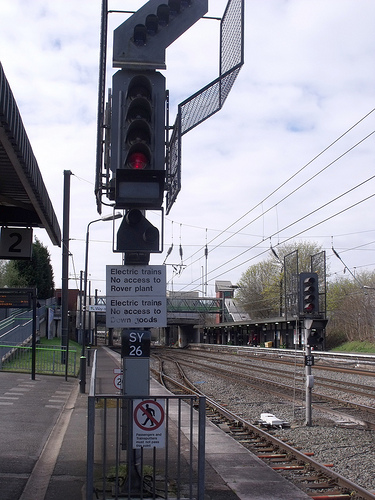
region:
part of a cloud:
[255, 73, 278, 116]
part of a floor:
[201, 435, 220, 456]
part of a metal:
[186, 450, 203, 490]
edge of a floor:
[230, 438, 250, 455]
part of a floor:
[231, 436, 262, 454]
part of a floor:
[246, 430, 274, 461]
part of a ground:
[313, 412, 339, 432]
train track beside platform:
[262, 445, 330, 490]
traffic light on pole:
[287, 260, 328, 350]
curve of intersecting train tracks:
[154, 351, 197, 379]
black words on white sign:
[104, 261, 169, 332]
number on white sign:
[3, 223, 29, 262]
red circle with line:
[127, 393, 169, 434]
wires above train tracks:
[237, 167, 357, 252]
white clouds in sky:
[280, 27, 349, 106]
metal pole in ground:
[292, 389, 322, 436]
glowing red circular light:
[117, 134, 160, 180]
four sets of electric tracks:
[168, 320, 374, 459]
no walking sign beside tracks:
[121, 399, 177, 462]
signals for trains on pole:
[287, 267, 330, 434]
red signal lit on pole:
[98, 4, 204, 257]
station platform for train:
[188, 312, 325, 357]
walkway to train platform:
[1, 287, 62, 372]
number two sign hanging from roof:
[5, 216, 38, 271]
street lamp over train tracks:
[77, 201, 117, 356]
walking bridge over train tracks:
[75, 289, 251, 328]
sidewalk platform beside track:
[89, 339, 180, 480]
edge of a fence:
[77, 444, 93, 467]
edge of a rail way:
[265, 421, 282, 427]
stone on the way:
[334, 432, 344, 437]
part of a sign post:
[148, 372, 149, 383]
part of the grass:
[337, 330, 346, 340]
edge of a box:
[119, 355, 124, 379]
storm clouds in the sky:
[262, 72, 319, 130]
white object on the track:
[244, 395, 287, 431]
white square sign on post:
[126, 397, 179, 455]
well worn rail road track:
[188, 395, 322, 485]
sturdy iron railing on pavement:
[74, 382, 218, 469]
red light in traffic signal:
[89, 142, 182, 176]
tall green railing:
[1, 336, 85, 369]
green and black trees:
[242, 236, 352, 313]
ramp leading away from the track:
[7, 299, 56, 354]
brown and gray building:
[209, 267, 240, 306]